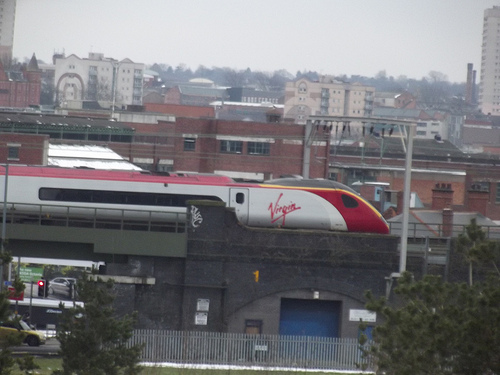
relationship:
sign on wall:
[195, 296, 210, 311] [99, 204, 446, 332]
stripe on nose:
[253, 177, 353, 193] [375, 207, 390, 234]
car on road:
[46, 275, 93, 299] [16, 277, 51, 292]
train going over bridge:
[1, 158, 393, 233] [0, 197, 499, 340]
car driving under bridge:
[1, 312, 47, 348] [0, 197, 499, 340]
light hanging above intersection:
[33, 279, 45, 289] [20, 266, 76, 355]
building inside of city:
[43, 44, 150, 104] [8, 22, 493, 372]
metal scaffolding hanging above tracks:
[301, 107, 418, 268] [256, 212, 486, 271]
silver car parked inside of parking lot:
[45, 275, 78, 296] [5, 278, 77, 298]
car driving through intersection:
[1, 314, 47, 348] [13, 288, 74, 355]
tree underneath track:
[58, 275, 145, 373] [2, 210, 497, 270]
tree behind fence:
[58, 275, 145, 373] [120, 326, 390, 373]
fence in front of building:
[120, 326, 390, 373] [52, 53, 143, 112]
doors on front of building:
[275, 294, 343, 368] [189, 245, 386, 345]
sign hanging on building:
[344, 308, 379, 324] [216, 266, 390, 340]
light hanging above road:
[37, 280, 44, 287] [22, 339, 61, 353]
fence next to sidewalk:
[120, 326, 390, 373] [144, 365, 358, 372]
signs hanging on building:
[193, 287, 219, 330] [147, 249, 387, 342]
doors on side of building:
[275, 294, 343, 368] [181, 239, 392, 339]